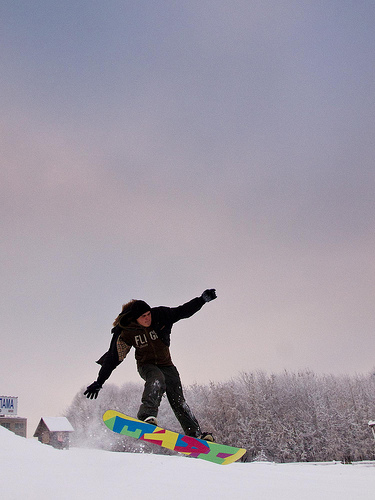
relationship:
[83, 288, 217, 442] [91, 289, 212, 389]
boarder wearing clothes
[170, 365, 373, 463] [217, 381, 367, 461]
trees covered with snow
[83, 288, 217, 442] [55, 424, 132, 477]
boarder kicking up snow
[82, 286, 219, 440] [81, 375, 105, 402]
snowboarder wearing glove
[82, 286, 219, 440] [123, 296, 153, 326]
snowboarder wearing hat